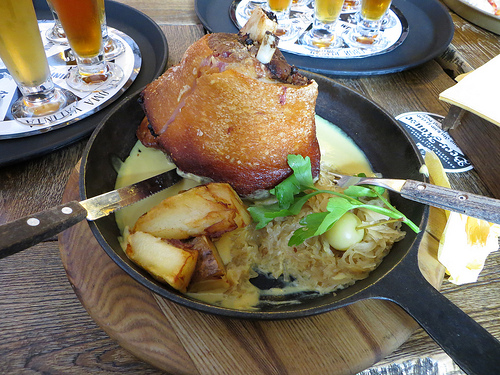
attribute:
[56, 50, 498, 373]
pan — on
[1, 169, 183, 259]
knife — serrated 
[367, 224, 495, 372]
handle — black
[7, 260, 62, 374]
table —  wood 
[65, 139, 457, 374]
board — round wood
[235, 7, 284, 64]
bone — in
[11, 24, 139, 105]
beer — on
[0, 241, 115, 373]
table top — wooden table 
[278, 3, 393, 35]
drinks tray —  serving 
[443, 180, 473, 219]
screw — Small silver 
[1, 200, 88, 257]
handle — on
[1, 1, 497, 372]
table top —  table 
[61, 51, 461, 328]
pan — black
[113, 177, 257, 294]
potatoes — cut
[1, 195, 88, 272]
handle — dark brown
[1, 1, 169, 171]
tray — on, round 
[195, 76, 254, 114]
skin — on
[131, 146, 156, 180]
sauce — in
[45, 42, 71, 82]
paper — in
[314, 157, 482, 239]
fork — on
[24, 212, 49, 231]
circle — on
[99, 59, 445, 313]
skillet — black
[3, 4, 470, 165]
platters — two black 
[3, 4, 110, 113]
glasses — beer